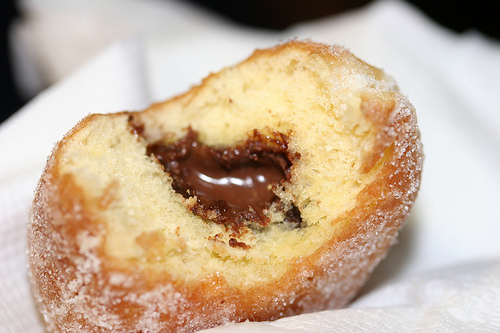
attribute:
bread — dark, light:
[22, 33, 423, 330]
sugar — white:
[378, 119, 424, 242]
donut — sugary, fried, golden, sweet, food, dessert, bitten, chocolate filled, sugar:
[27, 36, 427, 331]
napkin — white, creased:
[3, 1, 499, 330]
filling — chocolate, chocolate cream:
[144, 125, 306, 249]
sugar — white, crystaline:
[271, 36, 424, 310]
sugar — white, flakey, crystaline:
[23, 113, 240, 332]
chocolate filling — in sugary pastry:
[177, 143, 297, 208]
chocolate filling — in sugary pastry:
[174, 148, 298, 209]